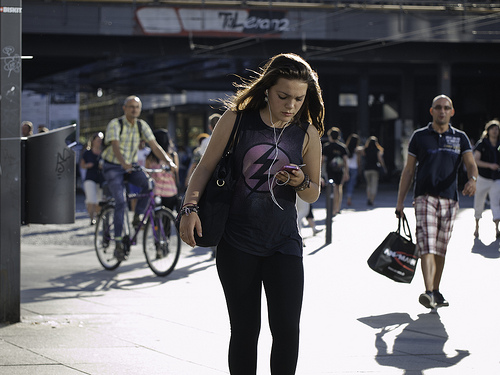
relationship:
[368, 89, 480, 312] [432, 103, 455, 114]
man wears glasses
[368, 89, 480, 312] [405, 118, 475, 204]
man wears shirt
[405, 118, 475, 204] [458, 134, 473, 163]
shirt has sleeve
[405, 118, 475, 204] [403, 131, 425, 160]
shirt has sleeve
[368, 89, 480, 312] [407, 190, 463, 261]
man wears shorts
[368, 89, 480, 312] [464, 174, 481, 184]
man wears watch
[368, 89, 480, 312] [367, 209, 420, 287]
man carries bag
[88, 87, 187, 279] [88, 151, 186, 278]
man on bike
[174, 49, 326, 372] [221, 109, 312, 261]
girl wears shirt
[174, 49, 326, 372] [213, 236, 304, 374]
girl wears leggings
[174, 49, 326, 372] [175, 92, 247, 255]
girl has purse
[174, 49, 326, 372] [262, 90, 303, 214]
girl wears earphones